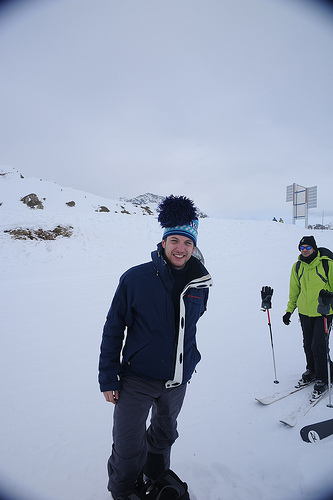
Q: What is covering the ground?
A: Snow.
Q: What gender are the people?
A: Male.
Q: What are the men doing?
A: Skiing.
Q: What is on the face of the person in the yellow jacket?
A: Sunglasses.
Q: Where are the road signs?
A: Top of the hill.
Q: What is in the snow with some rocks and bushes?
A: Hills.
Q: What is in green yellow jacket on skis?
A: A man.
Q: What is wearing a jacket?
A: A person.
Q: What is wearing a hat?
A: A person.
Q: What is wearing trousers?
A: A person.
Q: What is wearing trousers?
A: A person.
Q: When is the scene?
A: It is a daytime.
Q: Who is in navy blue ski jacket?
A: A man.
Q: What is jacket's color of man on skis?
A: Lime.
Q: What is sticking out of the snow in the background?
A: Rocks.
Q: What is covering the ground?
A: Snow.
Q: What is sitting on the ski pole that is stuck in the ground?
A: Ski glove.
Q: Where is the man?
A: Standing on the slope.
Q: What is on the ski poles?
A: Gloves.